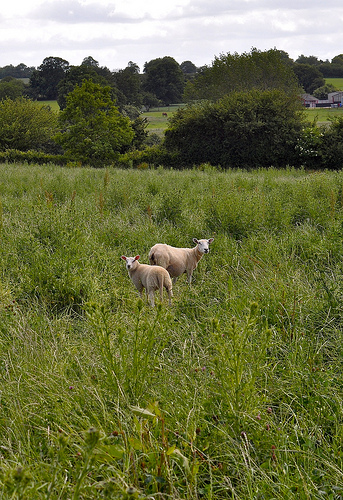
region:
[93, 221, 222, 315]
Sheep in a field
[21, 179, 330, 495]
Sheep in a grassy field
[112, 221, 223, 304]
Two sheep in a field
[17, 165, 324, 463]
Two sheep in a grassy field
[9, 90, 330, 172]
Trees near a grassy field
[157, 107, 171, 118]
A horse in a pasture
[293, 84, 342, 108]
A farm in the distance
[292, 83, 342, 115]
A barn in the distance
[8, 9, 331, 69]
Clouds above the trees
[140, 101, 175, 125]
A horse in a pasture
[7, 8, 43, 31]
white clouds in blue sky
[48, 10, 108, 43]
white clouds in blue sky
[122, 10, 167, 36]
white clouds in blue sky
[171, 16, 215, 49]
white clouds in blue sky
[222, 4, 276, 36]
white clouds in blue sky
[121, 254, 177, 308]
brown and white sheep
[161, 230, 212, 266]
brown and white sheep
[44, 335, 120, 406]
long green and brown grass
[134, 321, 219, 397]
long green and brown grass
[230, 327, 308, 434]
long green and brown grass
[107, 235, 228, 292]
two sheep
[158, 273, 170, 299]
the sheeps tail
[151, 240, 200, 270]
the sheep is light brown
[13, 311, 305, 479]
the grass is tall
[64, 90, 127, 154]
the tall green bushes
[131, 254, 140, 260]
ear of the sheep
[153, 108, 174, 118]
animal in the field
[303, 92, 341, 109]
a barn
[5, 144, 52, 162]
the green bushes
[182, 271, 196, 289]
the sheep leg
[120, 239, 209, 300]
two sheep in a grassy field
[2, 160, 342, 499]
large green grassy field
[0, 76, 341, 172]
hill with trees and a house in the background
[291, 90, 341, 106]
gray house in the background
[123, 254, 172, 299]
lamb is looking at the camera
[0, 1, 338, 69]
the sky is mostly cloudy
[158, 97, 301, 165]
large green tree in the background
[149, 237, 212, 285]
lamb is looking to the side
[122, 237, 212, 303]
two sheep looking back at the camera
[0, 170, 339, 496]
large grassy area for sheep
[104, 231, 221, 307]
The sheep in the grass.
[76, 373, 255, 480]
The green grass is tall.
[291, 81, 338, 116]
Buildings behind the trees.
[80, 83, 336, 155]
The trees are green.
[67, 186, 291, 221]
Bushes in the grass.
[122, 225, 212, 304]
Two sheeps in the field.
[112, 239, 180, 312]
The sheep is brown.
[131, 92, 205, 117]
a fence in the background.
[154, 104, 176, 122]
A horse in the field.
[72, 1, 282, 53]
The sky has clouds.